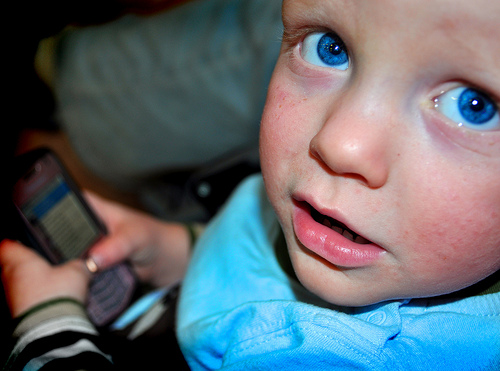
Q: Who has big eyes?
A: The child.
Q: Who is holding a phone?
A: Child.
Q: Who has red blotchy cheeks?
A: The boy.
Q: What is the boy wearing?
A: A blue and striped shirt.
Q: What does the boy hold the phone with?
A: His hands.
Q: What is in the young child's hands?
A: A phone.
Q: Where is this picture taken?
A: In a car.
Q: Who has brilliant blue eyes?
A: The young child.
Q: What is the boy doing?
A: Playing with a cellphone.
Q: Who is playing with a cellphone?
A: A young boy.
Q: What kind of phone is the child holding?
A: A cellphone.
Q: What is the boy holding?
A: Cellphone.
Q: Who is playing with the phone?
A: The boy.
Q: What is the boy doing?
A: Playing.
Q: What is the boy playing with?
A: Cellphone.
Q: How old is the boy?
A: Young.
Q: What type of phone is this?
A: Cell.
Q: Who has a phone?
A: The boy.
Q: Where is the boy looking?
A: Up.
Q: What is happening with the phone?
A: Being played with.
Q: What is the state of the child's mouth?
A: Open.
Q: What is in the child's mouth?
A: Teeth.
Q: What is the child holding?
A: Cell phone.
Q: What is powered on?
A: Cell phone.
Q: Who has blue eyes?
A: The child.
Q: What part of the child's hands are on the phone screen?
A: Thumbs.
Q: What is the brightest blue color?
A: Child's eyes.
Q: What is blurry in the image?
A: Background.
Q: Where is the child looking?
A: Right and upward.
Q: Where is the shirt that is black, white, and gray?
A: On the arms closest to the phone.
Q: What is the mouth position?
A: Open.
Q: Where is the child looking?
A: Camera.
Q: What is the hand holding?
A: Phone.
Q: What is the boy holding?
A: Phone.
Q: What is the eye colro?
A: Blue.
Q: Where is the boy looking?
A: Shoulder.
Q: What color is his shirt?
A: Blue.